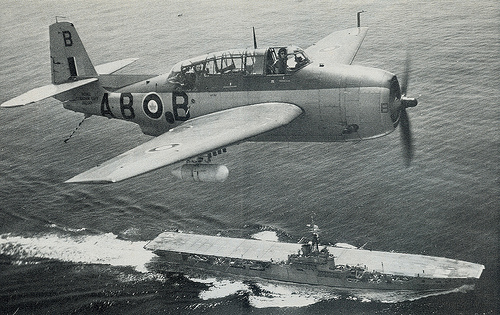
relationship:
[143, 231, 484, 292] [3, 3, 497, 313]
aircraft carrier on water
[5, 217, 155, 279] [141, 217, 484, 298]
wave behind aicraft carrier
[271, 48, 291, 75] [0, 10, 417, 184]
pilot in aircraft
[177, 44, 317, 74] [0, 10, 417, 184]
cockpit of aircraft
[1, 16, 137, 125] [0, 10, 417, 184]
tail of aircraft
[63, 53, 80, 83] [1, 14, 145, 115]
stripe in tail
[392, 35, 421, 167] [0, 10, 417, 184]
propeller in aircraft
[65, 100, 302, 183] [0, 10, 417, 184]
wing in aircraft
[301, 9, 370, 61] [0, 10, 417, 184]
wing in aircraft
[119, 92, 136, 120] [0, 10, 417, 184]
letter in aircraft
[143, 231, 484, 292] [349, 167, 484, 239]
aircraft carrier in water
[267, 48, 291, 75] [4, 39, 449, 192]
pilot in airplane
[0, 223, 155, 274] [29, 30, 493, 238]
wave in water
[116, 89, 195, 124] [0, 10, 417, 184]
bob in aircraft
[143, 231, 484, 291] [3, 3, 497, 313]
aircraft carrier in water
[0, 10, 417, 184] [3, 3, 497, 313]
aircraft in water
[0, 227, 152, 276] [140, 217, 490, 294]
wake in ship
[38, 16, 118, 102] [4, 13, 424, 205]
tailfin in plane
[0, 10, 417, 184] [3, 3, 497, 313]
aircraft flying above water